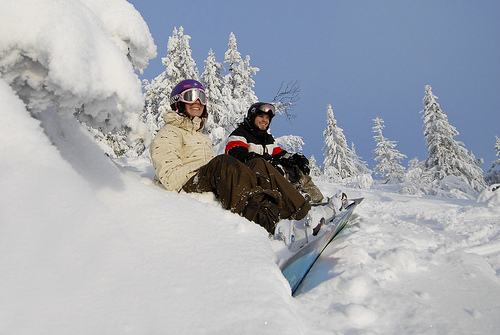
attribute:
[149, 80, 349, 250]
couple — snowboarding, sitting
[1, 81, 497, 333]
snow — undisturbed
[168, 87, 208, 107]
goggles — pink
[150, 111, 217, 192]
coat — white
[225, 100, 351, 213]
man — smiling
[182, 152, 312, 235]
pants — black, brown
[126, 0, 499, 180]
sky — blue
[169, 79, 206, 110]
helmet — purple